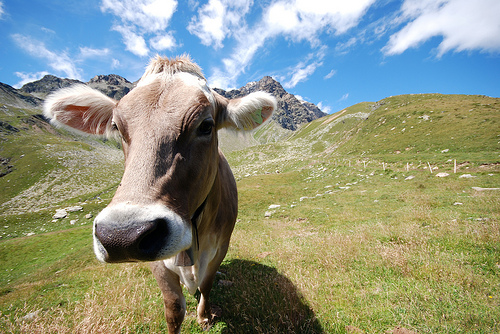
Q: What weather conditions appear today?
A: It is cloudy.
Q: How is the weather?
A: It is cloudy.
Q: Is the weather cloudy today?
A: Yes, it is cloudy.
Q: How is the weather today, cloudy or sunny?
A: It is cloudy.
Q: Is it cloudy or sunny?
A: It is cloudy.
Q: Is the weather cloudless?
A: No, it is cloudy.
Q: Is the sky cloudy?
A: Yes, the sky is cloudy.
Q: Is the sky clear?
A: No, the sky is cloudy.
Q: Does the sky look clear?
A: No, the sky is cloudy.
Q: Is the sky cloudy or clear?
A: The sky is cloudy.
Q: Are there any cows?
A: Yes, there is a cow.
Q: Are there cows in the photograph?
A: Yes, there is a cow.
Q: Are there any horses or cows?
A: Yes, there is a cow.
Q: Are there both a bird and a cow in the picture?
A: No, there is a cow but no birds.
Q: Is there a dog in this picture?
A: No, there are no dogs.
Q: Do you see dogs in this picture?
A: No, there are no dogs.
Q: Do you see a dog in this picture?
A: No, there are no dogs.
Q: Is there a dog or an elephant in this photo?
A: No, there are no dogs or elephants.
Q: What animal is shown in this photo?
A: The animal is a cow.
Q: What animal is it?
A: The animal is a cow.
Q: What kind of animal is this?
A: This is a cow.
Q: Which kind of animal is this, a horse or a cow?
A: This is a cow.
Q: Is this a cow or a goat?
A: This is a cow.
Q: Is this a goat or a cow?
A: This is a cow.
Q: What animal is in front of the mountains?
A: The cow is in front of the mountains.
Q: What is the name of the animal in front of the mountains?
A: The animal is a cow.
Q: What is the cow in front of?
A: The cow is in front of the mountains.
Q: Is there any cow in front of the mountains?
A: Yes, there is a cow in front of the mountains.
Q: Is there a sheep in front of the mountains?
A: No, there is a cow in front of the mountains.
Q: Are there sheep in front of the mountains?
A: No, there is a cow in front of the mountains.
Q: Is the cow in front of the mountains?
A: Yes, the cow is in front of the mountains.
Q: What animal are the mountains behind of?
A: The mountains are behind the cow.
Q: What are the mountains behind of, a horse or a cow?
A: The mountains are behind a cow.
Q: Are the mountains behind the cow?
A: Yes, the mountains are behind the cow.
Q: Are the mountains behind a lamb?
A: No, the mountains are behind the cow.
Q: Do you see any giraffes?
A: No, there are no giraffes.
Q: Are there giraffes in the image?
A: No, there are no giraffes.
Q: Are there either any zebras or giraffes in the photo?
A: No, there are no giraffes or zebras.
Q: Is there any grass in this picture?
A: Yes, there is grass.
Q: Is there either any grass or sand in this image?
A: Yes, there is grass.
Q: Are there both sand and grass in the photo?
A: No, there is grass but no sand.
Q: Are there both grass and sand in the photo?
A: No, there is grass but no sand.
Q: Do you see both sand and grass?
A: No, there is grass but no sand.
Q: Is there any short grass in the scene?
A: Yes, there is short grass.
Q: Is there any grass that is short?
A: Yes, there is grass that is short.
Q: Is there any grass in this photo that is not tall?
A: Yes, there is short grass.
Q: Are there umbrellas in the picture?
A: No, there are no umbrellas.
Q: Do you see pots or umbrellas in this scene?
A: No, there are no umbrellas or pots.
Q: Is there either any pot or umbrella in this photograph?
A: No, there are no umbrellas or pots.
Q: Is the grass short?
A: Yes, the grass is short.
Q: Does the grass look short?
A: Yes, the grass is short.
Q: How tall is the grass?
A: The grass is short.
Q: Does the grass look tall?
A: No, the grass is short.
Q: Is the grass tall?
A: No, the grass is short.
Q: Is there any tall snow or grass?
A: No, there is grass but it is short.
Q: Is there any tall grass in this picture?
A: No, there is grass but it is short.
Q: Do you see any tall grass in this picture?
A: No, there is grass but it is short.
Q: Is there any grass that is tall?
A: No, there is grass but it is short.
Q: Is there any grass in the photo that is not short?
A: No, there is grass but it is short.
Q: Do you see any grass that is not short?
A: No, there is grass but it is short.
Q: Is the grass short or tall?
A: The grass is short.